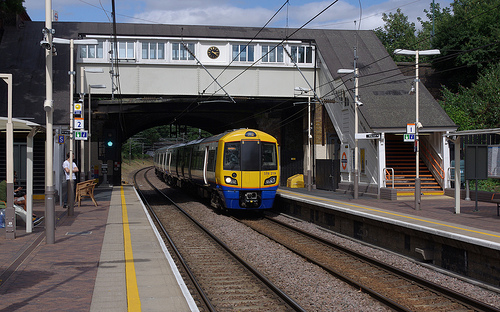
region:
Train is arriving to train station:
[140, 117, 290, 221]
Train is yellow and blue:
[148, 121, 285, 214]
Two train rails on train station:
[130, 168, 499, 305]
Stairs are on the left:
[378, 127, 452, 202]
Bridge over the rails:
[72, 27, 317, 102]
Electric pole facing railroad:
[330, 52, 377, 199]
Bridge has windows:
[76, 34, 316, 68]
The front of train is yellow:
[211, 123, 287, 192]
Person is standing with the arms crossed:
[59, 145, 86, 215]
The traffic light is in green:
[103, 134, 118, 161]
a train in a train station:
[109, 99, 364, 303]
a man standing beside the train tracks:
[60, 145, 86, 206]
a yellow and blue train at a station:
[177, 105, 296, 211]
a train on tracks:
[178, 121, 303, 234]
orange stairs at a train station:
[382, 107, 456, 198]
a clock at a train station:
[194, 35, 236, 108]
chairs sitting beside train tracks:
[75, 165, 116, 206]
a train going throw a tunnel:
[105, 5, 314, 214]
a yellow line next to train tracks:
[95, 173, 160, 283]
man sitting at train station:
[7, 184, 48, 231]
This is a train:
[142, 97, 327, 261]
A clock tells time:
[176, 28, 319, 170]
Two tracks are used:
[122, 133, 340, 294]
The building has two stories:
[78, 21, 489, 231]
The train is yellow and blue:
[171, 108, 353, 274]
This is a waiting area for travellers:
[3, 104, 69, 291]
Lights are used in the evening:
[286, 50, 474, 170]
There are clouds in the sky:
[131, 11, 448, 173]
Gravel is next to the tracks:
[157, 194, 394, 306]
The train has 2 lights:
[209, 161, 356, 262]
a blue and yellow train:
[212, 127, 287, 217]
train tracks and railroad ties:
[184, 221, 249, 291]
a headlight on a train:
[223, 170, 240, 185]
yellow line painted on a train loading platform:
[108, 190, 143, 280]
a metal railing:
[425, 151, 445, 182]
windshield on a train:
[227, 135, 274, 172]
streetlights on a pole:
[395, 45, 440, 124]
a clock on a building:
[203, 44, 223, 61]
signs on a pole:
[68, 99, 94, 141]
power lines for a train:
[245, 15, 280, 70]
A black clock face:
[203, 40, 228, 65]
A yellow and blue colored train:
[151, 126, 281, 216]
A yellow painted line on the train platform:
[105, 178, 151, 310]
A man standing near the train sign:
[63, 153, 79, 211]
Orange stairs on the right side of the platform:
[386, 136, 446, 201]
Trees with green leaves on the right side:
[376, 0, 498, 127]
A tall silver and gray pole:
[43, 1, 61, 251]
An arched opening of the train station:
[124, 105, 216, 192]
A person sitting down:
[11, 180, 41, 230]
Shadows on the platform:
[0, 256, 140, 310]